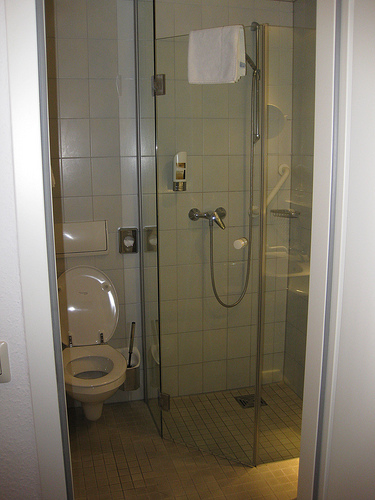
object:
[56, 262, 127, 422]
toilet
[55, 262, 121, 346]
lid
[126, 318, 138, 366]
brush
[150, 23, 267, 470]
door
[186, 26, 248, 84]
towel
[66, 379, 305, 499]
floor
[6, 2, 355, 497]
bathroom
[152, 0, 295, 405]
wall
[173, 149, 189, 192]
shampoo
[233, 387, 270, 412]
drain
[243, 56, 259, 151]
shower head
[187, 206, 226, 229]
faucet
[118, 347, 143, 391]
holder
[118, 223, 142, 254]
dispenser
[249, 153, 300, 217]
rail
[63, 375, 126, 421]
bowl